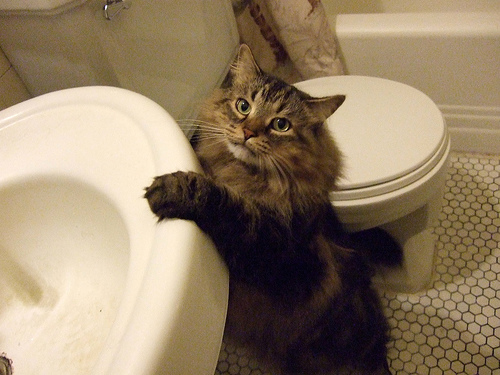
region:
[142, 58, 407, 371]
this is a cat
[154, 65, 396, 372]
the cat is brown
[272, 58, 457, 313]
this is a toilet seat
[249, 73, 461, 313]
the toilet sit is white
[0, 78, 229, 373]
this is a sink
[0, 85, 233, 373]
the sink is white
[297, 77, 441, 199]
this is a toilet sit cover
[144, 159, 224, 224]
the paw of a cat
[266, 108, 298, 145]
the eye of a cat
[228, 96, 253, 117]
the eye of a cat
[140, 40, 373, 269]
A cat with its paw on the sink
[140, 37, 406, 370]
A brown and grey tabby cat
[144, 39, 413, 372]
A cat standing on its back legs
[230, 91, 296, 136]
A cat with green eyes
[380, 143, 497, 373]
White hexagonal tile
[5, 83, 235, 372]
A white sink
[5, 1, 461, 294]
A white toilet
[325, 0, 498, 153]
A white bathtub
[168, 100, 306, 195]
A cat with long whiskers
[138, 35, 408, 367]
A fluffy cat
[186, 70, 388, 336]
cat is next to sink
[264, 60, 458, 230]
white toilet seat cover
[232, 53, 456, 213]
toilet seat cover is closed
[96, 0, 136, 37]
metal toilet flush handle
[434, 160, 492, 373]
white and brown hexagonal tile on floor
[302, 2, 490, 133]
white tub behind toilet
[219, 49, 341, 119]
cat has brown ears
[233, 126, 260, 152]
cat has dark brown nose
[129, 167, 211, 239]
cat has dark brown paws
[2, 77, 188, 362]
sink near cat is white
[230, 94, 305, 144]
Green eyes on the cat's face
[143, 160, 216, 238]
Cat's paw on the toilet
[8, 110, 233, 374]
White toilet in the bathroom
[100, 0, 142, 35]
Metal handle on the toilet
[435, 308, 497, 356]
White tiled bathroom floor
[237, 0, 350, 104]
A patterned shower curtain by the tub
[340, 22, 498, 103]
A white bathtub behind the toilet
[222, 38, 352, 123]
Two ears on the head of the cat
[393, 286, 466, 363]
Cat's shadow on the bathroom floor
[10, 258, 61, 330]
A shadow on the sink's interior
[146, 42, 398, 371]
The cat is brown and black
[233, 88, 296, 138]
The cat has green eyes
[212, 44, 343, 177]
The cat is looking at the camera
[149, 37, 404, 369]
The cat has one paw on the sink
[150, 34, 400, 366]
The cat has stripes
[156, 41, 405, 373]
The cat is standing on its hind legs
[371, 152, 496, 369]
The flooring is black and white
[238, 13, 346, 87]
The curtains are brown and white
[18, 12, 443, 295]
White toilet behind the cat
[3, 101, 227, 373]
The sink is round